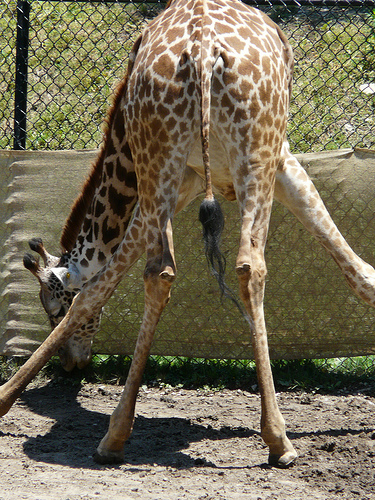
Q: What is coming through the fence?
A: Grass.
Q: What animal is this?
A: A giraffe.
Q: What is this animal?
A: Giraffe.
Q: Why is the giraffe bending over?
A: To eat grass.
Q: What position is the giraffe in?
A: Bent over with legs splayed.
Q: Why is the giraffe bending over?
A: To eat.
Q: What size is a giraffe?
A: Large.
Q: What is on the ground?
A: Dirt.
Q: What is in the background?
A: A chain link fence.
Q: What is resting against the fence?
A: A piece of cloth.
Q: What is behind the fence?
A: Grass.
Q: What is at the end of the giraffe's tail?
A: Black hair.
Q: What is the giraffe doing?
A: Eating grass.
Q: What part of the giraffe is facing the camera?
A: Back side.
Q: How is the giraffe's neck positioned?
A: Leaning down.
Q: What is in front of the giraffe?
A: Chain-link fence.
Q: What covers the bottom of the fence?
A: Tan-colored sheet.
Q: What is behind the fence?
A: Grass and dirt patches.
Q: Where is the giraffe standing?
A: On the dirt.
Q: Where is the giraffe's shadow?
A: On the dirt.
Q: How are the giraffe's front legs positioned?
A: Spread wide.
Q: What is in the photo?
A: An animal.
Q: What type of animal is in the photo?
A: A giraffe.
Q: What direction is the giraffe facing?
A: Away from the camera.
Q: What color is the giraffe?
A: Orange and white.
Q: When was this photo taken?
A: During the daytime.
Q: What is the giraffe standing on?
A: Dirt.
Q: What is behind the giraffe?
A: A fence.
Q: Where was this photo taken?
A: At a zoo.